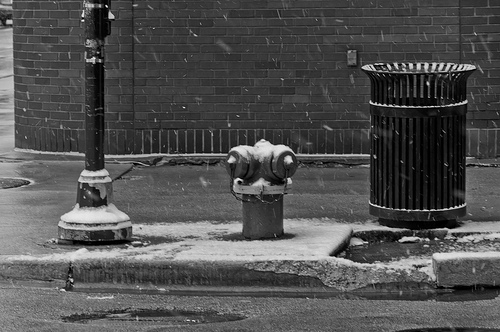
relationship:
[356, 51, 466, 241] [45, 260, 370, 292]
trash can on sidewalk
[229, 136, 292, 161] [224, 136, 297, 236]
snow on hydrant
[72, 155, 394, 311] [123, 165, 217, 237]
snow on sidewalk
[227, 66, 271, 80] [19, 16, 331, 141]
brick corner of building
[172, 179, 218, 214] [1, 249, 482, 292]
sidewalk near curb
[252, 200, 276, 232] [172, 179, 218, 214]
hydrant on sidewalk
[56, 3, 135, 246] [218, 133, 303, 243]
pole beside hyrdrant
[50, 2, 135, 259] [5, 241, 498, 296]
pole near curb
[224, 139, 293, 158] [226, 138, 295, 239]
snow on top of fire hydrant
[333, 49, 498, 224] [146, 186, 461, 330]
trash on sidewalk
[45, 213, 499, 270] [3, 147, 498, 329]
snow on ground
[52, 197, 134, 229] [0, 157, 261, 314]
snow on bottom of pole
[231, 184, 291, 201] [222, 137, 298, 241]
chains on fire hydrant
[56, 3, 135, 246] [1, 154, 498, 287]
pole on sidewalk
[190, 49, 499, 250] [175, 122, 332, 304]
can near a fire hyrdrant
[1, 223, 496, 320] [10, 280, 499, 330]
curb along road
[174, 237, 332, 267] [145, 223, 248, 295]
snow on ground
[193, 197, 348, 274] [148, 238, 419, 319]
snow on ground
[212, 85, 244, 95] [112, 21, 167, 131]
brick on wall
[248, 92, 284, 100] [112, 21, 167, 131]
brick on wall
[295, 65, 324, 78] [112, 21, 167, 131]
brick on wall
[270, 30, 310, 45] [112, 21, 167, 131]
brick on wall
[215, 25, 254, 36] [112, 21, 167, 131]
brick on wall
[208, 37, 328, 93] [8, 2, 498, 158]
brick on wall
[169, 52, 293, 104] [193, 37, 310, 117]
bricks on wall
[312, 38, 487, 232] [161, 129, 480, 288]
trash can on sidewalk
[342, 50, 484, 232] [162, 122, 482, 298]
trash can on sidewalk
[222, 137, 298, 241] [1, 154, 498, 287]
fire hydrant on sidewalk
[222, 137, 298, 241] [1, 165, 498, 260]
fire hydrant on sidewalk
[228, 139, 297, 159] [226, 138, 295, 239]
snow on fire hydrant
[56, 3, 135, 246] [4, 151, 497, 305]
pole on sidewalk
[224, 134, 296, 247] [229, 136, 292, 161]
hydrant covered in snow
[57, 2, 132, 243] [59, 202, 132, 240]
street light covered in snow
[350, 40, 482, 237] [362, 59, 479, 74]
bin covered in snow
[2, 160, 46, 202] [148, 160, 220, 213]
manhole cover on sidewalk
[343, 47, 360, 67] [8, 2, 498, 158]
box on wall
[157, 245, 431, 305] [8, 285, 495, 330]
curb beside street